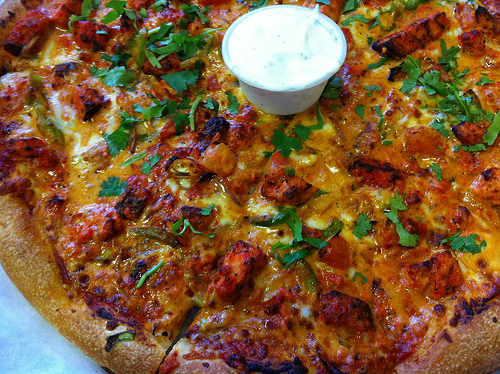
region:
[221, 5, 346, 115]
the small plastic container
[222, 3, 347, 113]
the white sauce in the container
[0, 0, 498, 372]
the whole cooked pizza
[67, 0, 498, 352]
the green vegetables on the pizza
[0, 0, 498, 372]
the crust on the pizza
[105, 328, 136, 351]
the burnt piece of a vegetable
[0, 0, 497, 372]
the cheese on the pizza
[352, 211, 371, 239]
the piece of cilantro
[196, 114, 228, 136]
the burnt piece near the container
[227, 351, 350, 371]
the burn area near the crust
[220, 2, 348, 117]
Ranch dressing in a container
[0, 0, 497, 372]
Pizza with a ranch container on it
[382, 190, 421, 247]
A piece of green garnish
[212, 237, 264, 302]
A piece of buffalo chicken on a pizza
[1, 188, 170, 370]
Crust on a pizza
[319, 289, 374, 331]
A piece of buffalo chicken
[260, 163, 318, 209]
A piece of buffalo chicken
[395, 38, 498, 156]
Green garnish on a pizza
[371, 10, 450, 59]
A piece of buffalo chicken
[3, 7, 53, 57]
A piece of buffalo chicken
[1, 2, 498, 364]
pizza covered in toppings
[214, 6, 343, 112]
dipping bowl sitting on pizza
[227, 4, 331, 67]
dip in the dipping bowl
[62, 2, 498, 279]
torn green seasoning leaves on the pizza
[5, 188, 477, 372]
golden brown crust of the pizza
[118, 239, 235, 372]
cut made in the pizza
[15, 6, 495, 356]
cheese on the pizza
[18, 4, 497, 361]
meat topping on the pizza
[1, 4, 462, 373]
sauce on the edges of the pizza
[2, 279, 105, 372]
white surface the pizza is on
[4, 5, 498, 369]
Round pizza and dip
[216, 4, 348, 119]
Plastic container of white dip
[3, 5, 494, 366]
Pizza with slightly burned toppings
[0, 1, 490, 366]
Pizza sprinkled with green parsley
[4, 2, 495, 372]
Pizza cut in to large slices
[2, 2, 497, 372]
Pizza sitting on white table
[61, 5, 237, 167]
Pile of chopped parsley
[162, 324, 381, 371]
Slightly blackened pizza crust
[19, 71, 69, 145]
Small slice of green pepper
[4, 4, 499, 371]
Pizza covered with red sauce and orange cheese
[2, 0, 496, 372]
pizza with stuff on it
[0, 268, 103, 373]
white thing under pizza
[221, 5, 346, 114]
a small plastic bowl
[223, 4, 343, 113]
ranch dip in bowl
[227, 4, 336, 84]
the dip is white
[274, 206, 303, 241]
green thing on pizza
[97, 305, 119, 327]
burned part of crust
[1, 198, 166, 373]
the crust is brown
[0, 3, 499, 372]
red sauce on pizza